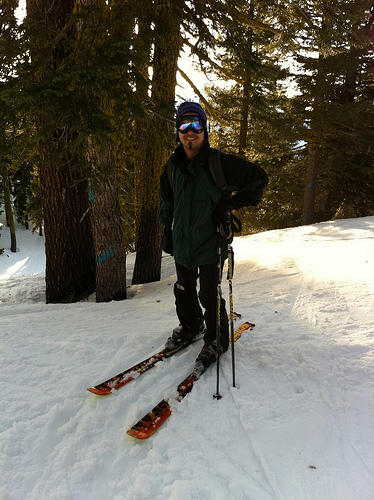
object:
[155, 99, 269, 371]
person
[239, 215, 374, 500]
mountains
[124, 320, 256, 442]
skis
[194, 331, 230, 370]
feet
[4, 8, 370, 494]
outdoors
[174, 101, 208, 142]
hat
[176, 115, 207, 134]
goggles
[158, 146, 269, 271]
jacket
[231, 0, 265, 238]
trees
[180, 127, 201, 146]
fun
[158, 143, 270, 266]
coat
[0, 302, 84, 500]
snow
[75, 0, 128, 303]
tree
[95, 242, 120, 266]
mark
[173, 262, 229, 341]
pants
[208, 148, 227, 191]
strap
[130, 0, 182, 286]
tree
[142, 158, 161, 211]
moss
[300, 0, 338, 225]
tree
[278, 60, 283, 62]
pine needles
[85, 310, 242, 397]
ski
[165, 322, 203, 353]
foot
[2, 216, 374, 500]
ground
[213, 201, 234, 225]
hand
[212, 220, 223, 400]
ski poles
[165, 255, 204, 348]
legs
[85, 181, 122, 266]
spray paint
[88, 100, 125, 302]
tree trunk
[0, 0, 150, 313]
tree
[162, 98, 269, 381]
skier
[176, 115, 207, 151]
face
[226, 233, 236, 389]
ski sticks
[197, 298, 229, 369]
snow boots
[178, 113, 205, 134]
sunglasses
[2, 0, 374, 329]
background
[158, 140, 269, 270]
snow jacket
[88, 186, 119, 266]
paint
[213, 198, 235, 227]
gloves